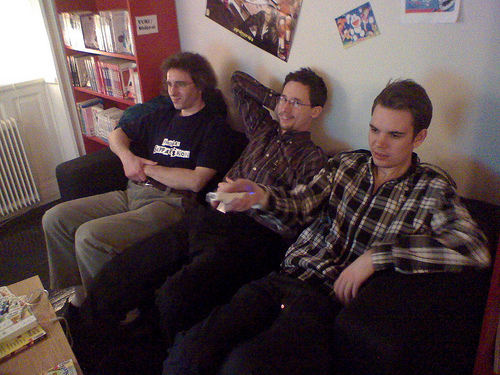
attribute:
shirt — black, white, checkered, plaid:
[258, 151, 492, 282]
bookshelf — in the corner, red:
[56, 2, 181, 157]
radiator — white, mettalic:
[0, 120, 41, 221]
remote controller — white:
[206, 191, 246, 205]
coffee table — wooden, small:
[2, 275, 78, 373]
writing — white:
[151, 136, 190, 160]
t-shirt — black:
[117, 110, 233, 188]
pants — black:
[165, 272, 332, 375]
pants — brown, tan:
[42, 181, 192, 294]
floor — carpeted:
[0, 201, 68, 289]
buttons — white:
[250, 138, 279, 176]